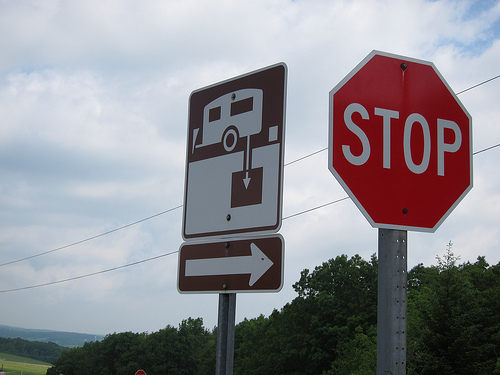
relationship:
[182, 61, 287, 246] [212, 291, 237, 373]
sign on pole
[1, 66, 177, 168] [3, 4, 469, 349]
cloud in sky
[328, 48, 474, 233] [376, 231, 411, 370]
stop sign on pole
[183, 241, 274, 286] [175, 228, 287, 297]
arrow on sign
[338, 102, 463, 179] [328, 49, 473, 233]
stop written on sign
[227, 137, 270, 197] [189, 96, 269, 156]
arrow coming out of camper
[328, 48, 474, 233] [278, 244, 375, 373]
stop sign by trees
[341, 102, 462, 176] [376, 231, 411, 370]
stop on pole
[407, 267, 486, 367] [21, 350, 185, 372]
tree by road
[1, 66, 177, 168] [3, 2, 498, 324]
cloud in sky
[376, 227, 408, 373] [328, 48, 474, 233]
metal post holding up stop sign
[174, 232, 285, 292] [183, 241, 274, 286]
sign has arrow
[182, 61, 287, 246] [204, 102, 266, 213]
sign indicating septic tank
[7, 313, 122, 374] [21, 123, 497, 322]
mountains are distance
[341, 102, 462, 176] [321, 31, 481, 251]
stop on sign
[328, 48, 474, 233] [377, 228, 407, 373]
stop sign on pole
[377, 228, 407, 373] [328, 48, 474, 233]
pole on stop sign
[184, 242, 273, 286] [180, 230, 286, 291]
arrow on sign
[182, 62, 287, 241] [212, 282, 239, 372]
sign on pole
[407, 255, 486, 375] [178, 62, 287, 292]
tree lined up behind signs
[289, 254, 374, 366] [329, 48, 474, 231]
trees lined up behind signs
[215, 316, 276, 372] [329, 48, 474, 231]
trees lined up behind signs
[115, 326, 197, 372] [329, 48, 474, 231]
trees lined up behind signs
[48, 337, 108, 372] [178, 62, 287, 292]
trees lined up behind signs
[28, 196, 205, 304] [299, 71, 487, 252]
powerlines behind sign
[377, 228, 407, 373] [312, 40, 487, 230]
pole holding sign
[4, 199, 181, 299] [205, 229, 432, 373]
wires overhead behind poles